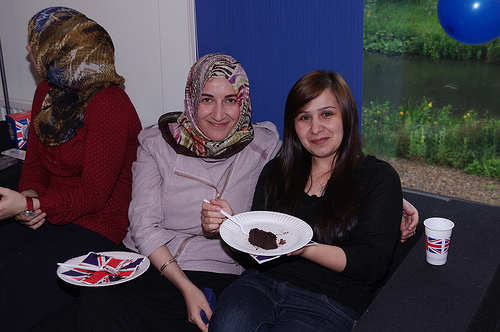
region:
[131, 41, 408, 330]
two woman pose for photo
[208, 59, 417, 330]
the woman on the right is eating cake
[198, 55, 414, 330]
the woman is using a plastic fork to eat the cake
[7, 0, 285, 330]
the two women on the left have scarfs over their heads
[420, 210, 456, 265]
a paper cup is on the table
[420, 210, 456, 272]
the paper cup has a picture of a British flag on it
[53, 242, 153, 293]
a paper plate with a napkin on it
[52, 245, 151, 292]
cake crumbs are on the napkin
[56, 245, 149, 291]
the napkin has a British flag design on it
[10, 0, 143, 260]
the woman on the left is wearing a red sweater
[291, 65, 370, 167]
Person has brown hair.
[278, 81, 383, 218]
Person has long hair.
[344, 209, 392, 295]
Person wearing black shirt.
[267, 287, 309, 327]
Person wearing blue jeans.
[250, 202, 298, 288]
Person holding white plate.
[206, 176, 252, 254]
Person holding white fork.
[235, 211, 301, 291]
Brown food on white plate.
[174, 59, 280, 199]
Person has material wrapped around head.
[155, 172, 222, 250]
Person wearing gray coat.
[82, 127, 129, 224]
Person wearing red shirt.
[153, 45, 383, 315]
Two women sitting together.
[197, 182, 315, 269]
Chocolate cake on a white plate.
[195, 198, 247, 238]
A fork in a woman's hand.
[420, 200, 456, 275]
A cup with a Brittish flag design on its side.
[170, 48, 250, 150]
A woman wearing a scarf on her head.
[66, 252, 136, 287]
A napkin designed with a Brittish flag.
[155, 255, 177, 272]
A silver bracelet on a woman's arm.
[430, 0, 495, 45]
A blue balloon near the window.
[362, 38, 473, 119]
A waterway outside of the window.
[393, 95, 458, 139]
Yellow flowers on the brush outside of the window.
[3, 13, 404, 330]
Women sitting on sofa.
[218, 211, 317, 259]
Woman holding white paper plate with chocolate cake in hand.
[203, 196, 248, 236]
White plastic fork in woman's hand.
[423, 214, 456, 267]
White paper cup with red and blue design sitting on arm of sofa.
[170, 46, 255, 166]
Woman wearing print scarf around head.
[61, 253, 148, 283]
Napkin with red, white and blue British flag design lying on plate.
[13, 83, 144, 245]
Woman dressed in red blouse.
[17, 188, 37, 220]
Woman wearing red watch around wrist.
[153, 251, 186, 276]
Woman wearing silver braclet around wrist.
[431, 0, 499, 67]
Blue balloon floating in air.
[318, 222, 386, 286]
Person wearing black shirt.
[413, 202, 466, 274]
White, red, and blue cup sitting on ledge.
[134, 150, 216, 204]
Person wearing gray shirt.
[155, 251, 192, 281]
Silver band around person's wrist.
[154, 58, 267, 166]
Woman has wrap around head.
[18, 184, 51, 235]
Red watch on person's wrist.